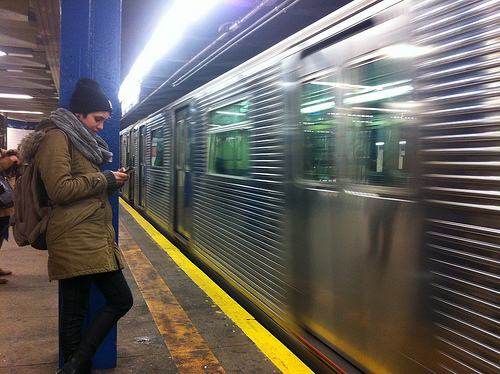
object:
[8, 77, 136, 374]
smiling woman